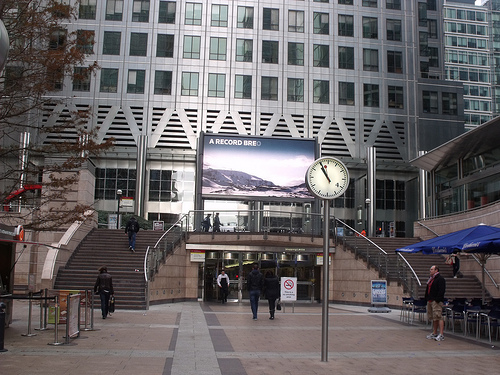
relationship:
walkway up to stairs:
[153, 290, 426, 374] [39, 207, 490, 309]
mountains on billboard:
[203, 162, 311, 199] [189, 124, 334, 204]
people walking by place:
[92, 264, 117, 321] [16, 299, 496, 374]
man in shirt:
[425, 264, 446, 342] [420, 269, 448, 305]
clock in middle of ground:
[280, 151, 370, 371] [0, 297, 497, 375]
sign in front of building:
[187, 124, 331, 241] [0, 1, 497, 311]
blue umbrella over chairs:
[396, 219, 498, 259] [400, 292, 498, 342]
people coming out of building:
[216, 269, 230, 304] [0, 1, 497, 311]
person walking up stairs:
[125, 216, 140, 252] [48, 218, 176, 308]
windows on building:
[2, 1, 499, 240] [0, 1, 497, 311]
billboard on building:
[190, 116, 356, 258] [4, 2, 499, 272]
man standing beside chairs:
[425, 264, 446, 342] [402, 294, 499, 345]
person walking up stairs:
[122, 213, 154, 255] [48, 218, 176, 308]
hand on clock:
[319, 162, 332, 183] [307, 154, 351, 362]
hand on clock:
[318, 167, 337, 187] [307, 154, 351, 362]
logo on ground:
[372, 281, 386, 302] [38, 308, 497, 373]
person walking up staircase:
[125, 216, 140, 252] [48, 218, 178, 309]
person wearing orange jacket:
[356, 220, 368, 244] [360, 225, 368, 237]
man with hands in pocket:
[417, 261, 458, 327] [428, 296, 440, 312]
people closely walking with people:
[246, 261, 266, 319] [261, 269, 282, 320]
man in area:
[425, 264, 446, 342] [7, 201, 473, 364]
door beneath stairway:
[192, 247, 341, 310] [48, 211, 452, 311]